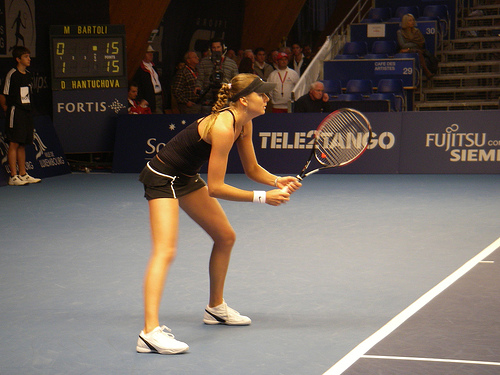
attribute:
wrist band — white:
[248, 187, 267, 205]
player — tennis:
[129, 62, 382, 367]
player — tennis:
[108, 53, 350, 363]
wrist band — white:
[252, 187, 272, 216]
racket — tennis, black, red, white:
[279, 102, 375, 194]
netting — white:
[324, 118, 364, 154]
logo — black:
[321, 115, 359, 161]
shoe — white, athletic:
[137, 326, 195, 358]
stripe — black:
[137, 333, 160, 352]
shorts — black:
[141, 152, 205, 205]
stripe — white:
[146, 159, 178, 183]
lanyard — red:
[274, 68, 294, 98]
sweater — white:
[261, 65, 301, 106]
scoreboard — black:
[46, 18, 128, 115]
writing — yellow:
[60, 76, 126, 88]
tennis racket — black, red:
[275, 101, 372, 192]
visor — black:
[226, 76, 284, 100]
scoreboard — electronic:
[42, 18, 130, 144]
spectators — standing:
[126, 32, 314, 123]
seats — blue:
[297, 72, 419, 111]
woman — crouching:
[126, 69, 303, 359]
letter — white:
[53, 98, 65, 116]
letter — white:
[64, 102, 73, 112]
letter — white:
[72, 100, 89, 112]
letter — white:
[84, 101, 96, 111]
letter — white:
[95, 96, 105, 112]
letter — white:
[448, 148, 463, 163]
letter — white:
[141, 133, 159, 154]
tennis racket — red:
[288, 99, 375, 188]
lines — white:
[325, 237, 499, 373]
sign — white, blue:
[56, 112, 496, 172]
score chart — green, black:
[47, 37, 122, 79]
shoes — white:
[135, 302, 250, 353]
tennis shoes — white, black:
[136, 301, 251, 353]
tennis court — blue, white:
[3, 174, 497, 372]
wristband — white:
[252, 190, 266, 206]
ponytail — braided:
[206, 79, 231, 112]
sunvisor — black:
[226, 76, 279, 101]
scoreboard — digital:
[46, 22, 127, 92]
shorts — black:
[136, 156, 207, 201]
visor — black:
[229, 78, 279, 101]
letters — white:
[258, 128, 394, 153]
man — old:
[290, 79, 328, 110]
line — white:
[318, 234, 498, 373]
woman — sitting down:
[372, 14, 444, 65]